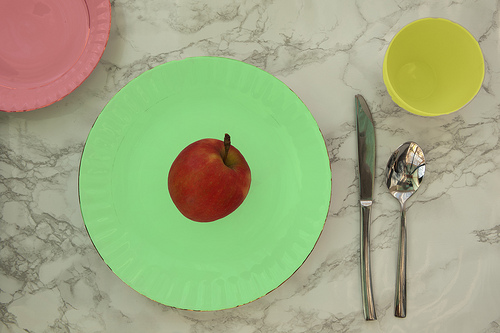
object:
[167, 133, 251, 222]
apple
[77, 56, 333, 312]
plate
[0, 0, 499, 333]
table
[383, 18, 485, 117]
cup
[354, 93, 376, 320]
knife